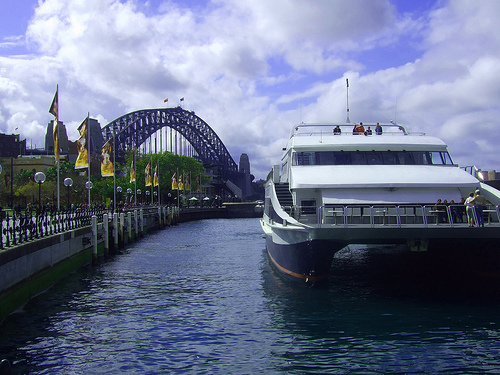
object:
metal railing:
[0, 204, 186, 254]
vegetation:
[0, 150, 218, 219]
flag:
[127, 157, 139, 206]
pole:
[133, 180, 141, 238]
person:
[462, 191, 476, 227]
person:
[373, 122, 381, 135]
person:
[354, 120, 364, 134]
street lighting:
[62, 176, 75, 228]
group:
[283, 124, 448, 152]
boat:
[258, 121, 499, 291]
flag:
[74, 112, 93, 209]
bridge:
[0, 204, 183, 292]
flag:
[47, 84, 63, 210]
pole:
[52, 88, 65, 210]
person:
[465, 189, 492, 228]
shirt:
[467, 194, 490, 207]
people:
[331, 123, 340, 137]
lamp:
[32, 170, 49, 227]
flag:
[150, 164, 163, 204]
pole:
[155, 186, 160, 207]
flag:
[178, 96, 184, 107]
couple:
[460, 188, 484, 230]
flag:
[141, 161, 155, 207]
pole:
[154, 160, 163, 207]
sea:
[0, 209, 499, 375]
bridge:
[98, 106, 239, 189]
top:
[141, 108, 204, 132]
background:
[0, 0, 499, 373]